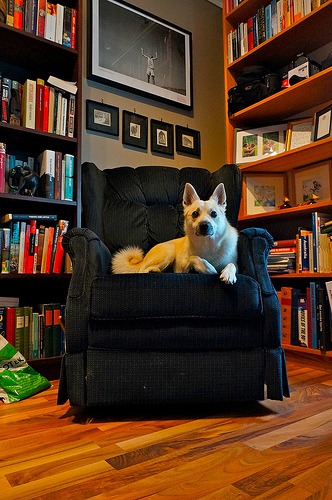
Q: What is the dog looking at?
A: The camera.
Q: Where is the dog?
A: On a chair.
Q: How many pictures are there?
A: Five.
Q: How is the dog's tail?
A: Curled up.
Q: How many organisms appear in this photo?
A: One.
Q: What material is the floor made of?
A: Wood.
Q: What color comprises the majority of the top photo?
A: Gray.